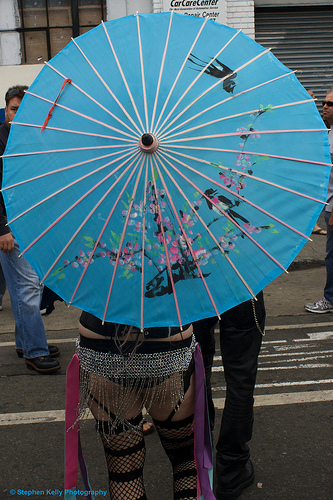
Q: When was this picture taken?
A: Daytime.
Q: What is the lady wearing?
A: Fishnet stockings.